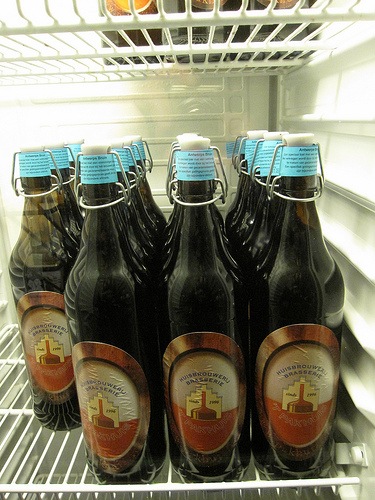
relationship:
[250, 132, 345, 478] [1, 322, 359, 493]
bottle on shelf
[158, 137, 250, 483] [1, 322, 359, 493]
bottle on shelf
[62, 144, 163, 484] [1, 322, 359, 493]
bottle on shelf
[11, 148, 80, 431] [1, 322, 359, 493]
bottle on shelf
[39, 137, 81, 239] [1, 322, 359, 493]
bottle on shelf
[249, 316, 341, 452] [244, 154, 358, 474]
label on bottle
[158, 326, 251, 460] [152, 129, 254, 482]
label on bottle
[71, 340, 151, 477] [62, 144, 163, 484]
label on bottle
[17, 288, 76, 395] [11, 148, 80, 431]
label on bottle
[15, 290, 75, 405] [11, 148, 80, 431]
label on bottle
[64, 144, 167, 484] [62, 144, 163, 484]
bottle on bottle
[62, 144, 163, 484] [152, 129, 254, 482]
bottle on bottle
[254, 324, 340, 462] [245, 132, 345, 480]
label on bottle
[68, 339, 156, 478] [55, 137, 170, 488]
label on bottle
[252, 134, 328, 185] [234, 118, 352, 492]
lable on bottle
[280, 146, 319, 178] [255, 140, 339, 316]
lable on bottle